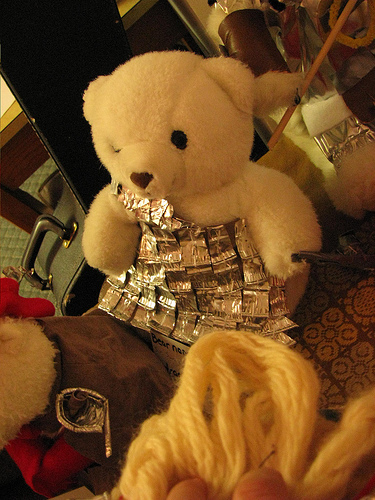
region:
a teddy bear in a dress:
[43, 66, 301, 377]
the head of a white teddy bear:
[70, 23, 252, 205]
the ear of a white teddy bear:
[196, 53, 257, 117]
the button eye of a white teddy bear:
[150, 123, 208, 151]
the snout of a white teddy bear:
[115, 147, 177, 202]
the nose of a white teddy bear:
[130, 161, 151, 188]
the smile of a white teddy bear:
[156, 175, 181, 196]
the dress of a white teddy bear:
[121, 197, 264, 329]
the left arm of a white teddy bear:
[253, 201, 338, 284]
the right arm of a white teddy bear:
[71, 182, 155, 268]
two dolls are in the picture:
[6, 84, 337, 432]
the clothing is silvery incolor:
[170, 227, 278, 351]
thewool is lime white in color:
[179, 348, 331, 486]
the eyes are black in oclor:
[82, 125, 222, 173]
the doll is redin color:
[9, 273, 72, 347]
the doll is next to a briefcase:
[27, 199, 152, 322]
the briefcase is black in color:
[25, 208, 101, 309]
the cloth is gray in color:
[73, 324, 147, 425]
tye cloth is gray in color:
[301, 303, 370, 387]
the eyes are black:
[165, 128, 193, 151]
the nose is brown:
[134, 169, 152, 187]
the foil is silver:
[132, 209, 253, 331]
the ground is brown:
[329, 297, 366, 363]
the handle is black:
[11, 216, 66, 277]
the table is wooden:
[6, 117, 35, 203]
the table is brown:
[2, 122, 41, 217]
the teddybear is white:
[96, 60, 331, 313]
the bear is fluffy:
[87, 62, 322, 321]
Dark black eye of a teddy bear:
[166, 128, 190, 153]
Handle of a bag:
[18, 208, 79, 294]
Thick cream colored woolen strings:
[102, 325, 373, 499]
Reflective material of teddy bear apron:
[93, 178, 299, 359]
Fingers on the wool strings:
[107, 448, 356, 498]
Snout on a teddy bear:
[128, 172, 167, 200]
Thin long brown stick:
[258, 0, 373, 151]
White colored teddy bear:
[64, 44, 329, 325]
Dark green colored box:
[20, 171, 106, 318]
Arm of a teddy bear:
[77, 180, 145, 279]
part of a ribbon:
[181, 341, 202, 368]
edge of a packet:
[86, 413, 102, 434]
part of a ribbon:
[214, 376, 233, 418]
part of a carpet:
[340, 347, 359, 370]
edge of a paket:
[93, 417, 110, 463]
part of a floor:
[304, 357, 342, 415]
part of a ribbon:
[154, 409, 173, 448]